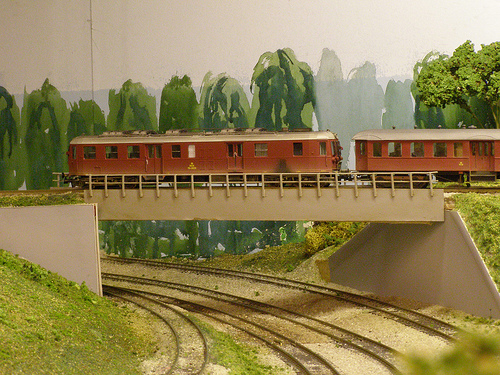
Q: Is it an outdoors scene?
A: Yes, it is outdoors.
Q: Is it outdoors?
A: Yes, it is outdoors.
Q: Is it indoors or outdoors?
A: It is outdoors.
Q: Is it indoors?
A: No, it is outdoors.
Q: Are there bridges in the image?
A: Yes, there is a bridge.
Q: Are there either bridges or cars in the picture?
A: Yes, there is a bridge.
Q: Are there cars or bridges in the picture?
A: Yes, there is a bridge.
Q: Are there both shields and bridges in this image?
A: No, there is a bridge but no shields.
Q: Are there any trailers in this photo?
A: No, there are no trailers.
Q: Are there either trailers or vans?
A: No, there are no trailers or vans.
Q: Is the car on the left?
A: No, the car is on the right of the image.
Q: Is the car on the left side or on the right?
A: The car is on the right of the image.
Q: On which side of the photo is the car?
A: The car is on the right of the image.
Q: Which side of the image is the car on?
A: The car is on the right of the image.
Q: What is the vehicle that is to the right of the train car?
A: The vehicle is a car.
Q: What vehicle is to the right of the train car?
A: The vehicle is a car.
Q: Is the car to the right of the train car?
A: Yes, the car is to the right of the train car.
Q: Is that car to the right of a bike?
A: No, the car is to the right of the train car.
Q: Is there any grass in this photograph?
A: Yes, there is grass.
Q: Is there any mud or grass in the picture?
A: Yes, there is grass.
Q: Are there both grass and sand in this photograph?
A: No, there is grass but no sand.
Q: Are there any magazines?
A: No, there are no magazines.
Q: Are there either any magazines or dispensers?
A: No, there are no magazines or dispensers.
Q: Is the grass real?
A: Yes, the grass is real.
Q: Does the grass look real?
A: Yes, the grass is real.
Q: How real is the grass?
A: The grass is real.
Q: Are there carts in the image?
A: No, there are no carts.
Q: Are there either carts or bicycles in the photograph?
A: No, there are no carts or bicycles.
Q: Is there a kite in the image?
A: No, there are no kites.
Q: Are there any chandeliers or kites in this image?
A: No, there are no kites or chandeliers.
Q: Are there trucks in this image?
A: No, there are no trucks.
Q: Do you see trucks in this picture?
A: No, there are no trucks.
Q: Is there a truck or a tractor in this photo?
A: No, there are no trucks or tractors.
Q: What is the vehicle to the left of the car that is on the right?
A: The vehicle is a train car.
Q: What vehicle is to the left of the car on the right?
A: The vehicle is a train car.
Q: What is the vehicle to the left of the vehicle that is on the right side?
A: The vehicle is a train car.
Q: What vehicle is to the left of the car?
A: The vehicle is a train car.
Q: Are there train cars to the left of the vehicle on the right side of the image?
A: Yes, there is a train car to the left of the car.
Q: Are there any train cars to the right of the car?
A: No, the train car is to the left of the car.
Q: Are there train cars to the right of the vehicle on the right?
A: No, the train car is to the left of the car.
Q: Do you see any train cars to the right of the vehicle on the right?
A: No, the train car is to the left of the car.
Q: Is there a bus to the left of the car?
A: No, there is a train car to the left of the car.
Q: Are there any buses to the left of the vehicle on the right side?
A: No, there is a train car to the left of the car.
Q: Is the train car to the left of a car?
A: Yes, the train car is to the left of a car.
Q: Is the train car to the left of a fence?
A: No, the train car is to the left of a car.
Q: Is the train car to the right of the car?
A: No, the train car is to the left of the car.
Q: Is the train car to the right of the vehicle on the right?
A: No, the train car is to the left of the car.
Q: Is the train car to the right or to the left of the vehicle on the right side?
A: The train car is to the left of the car.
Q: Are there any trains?
A: Yes, there is a train.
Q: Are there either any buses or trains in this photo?
A: Yes, there is a train.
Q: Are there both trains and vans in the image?
A: No, there is a train but no vans.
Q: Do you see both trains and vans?
A: No, there is a train but no vans.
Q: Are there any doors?
A: Yes, there is a door.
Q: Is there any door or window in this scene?
A: Yes, there is a door.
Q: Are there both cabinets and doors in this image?
A: No, there is a door but no cabinets.